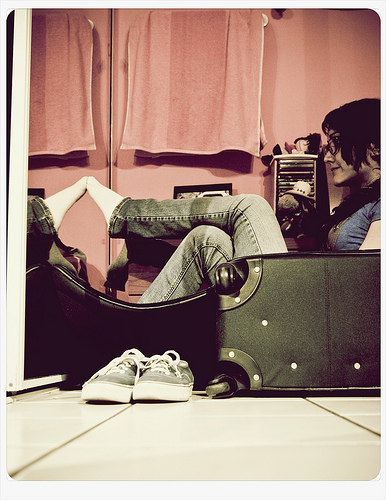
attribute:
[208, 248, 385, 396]
luggage — black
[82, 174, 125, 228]
sock — white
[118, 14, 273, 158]
towel — pink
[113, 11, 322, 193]
wall — pink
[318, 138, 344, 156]
glasses — black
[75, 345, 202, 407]
sneakers — white, grey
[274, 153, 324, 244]
tower — assorted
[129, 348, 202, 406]
shoe — blue, white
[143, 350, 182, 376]
strings — white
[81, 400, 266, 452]
tile — white